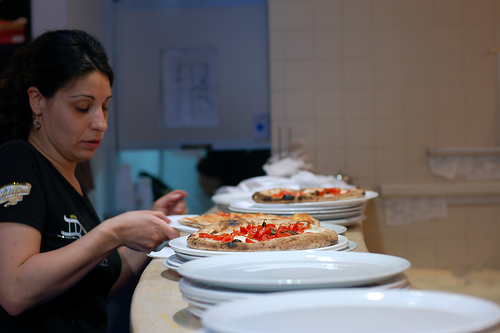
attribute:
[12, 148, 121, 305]
shirt — black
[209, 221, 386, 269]
toppings — Tomato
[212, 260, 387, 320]
plates — white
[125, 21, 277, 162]
wall — blue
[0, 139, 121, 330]
shirt — black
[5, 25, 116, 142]
hair — dark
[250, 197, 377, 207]
plate — white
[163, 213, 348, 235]
plate — white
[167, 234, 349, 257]
plate — white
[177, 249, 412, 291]
plate — white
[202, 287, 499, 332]
plate — white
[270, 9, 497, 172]
wall — white, tiled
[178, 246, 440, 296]
plate — white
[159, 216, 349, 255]
plate — white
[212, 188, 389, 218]
plate — white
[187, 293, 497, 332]
plate — white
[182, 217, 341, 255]
pizza — fresh, baked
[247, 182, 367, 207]
pizza — fresh, baked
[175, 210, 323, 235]
pizza — fresh, baked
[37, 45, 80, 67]
hair — black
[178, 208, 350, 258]
pizza — small, fresh, baked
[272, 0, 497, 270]
wall — tan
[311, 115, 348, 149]
tile — Beige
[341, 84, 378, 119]
tile — Beige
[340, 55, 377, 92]
tile — Beige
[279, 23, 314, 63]
tile — Beige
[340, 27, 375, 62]
tile — Beige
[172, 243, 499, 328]
plates — white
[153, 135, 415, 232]
plates — white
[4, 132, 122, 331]
t-shirt — black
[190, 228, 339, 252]
crust — black, burnt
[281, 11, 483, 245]
tile — white